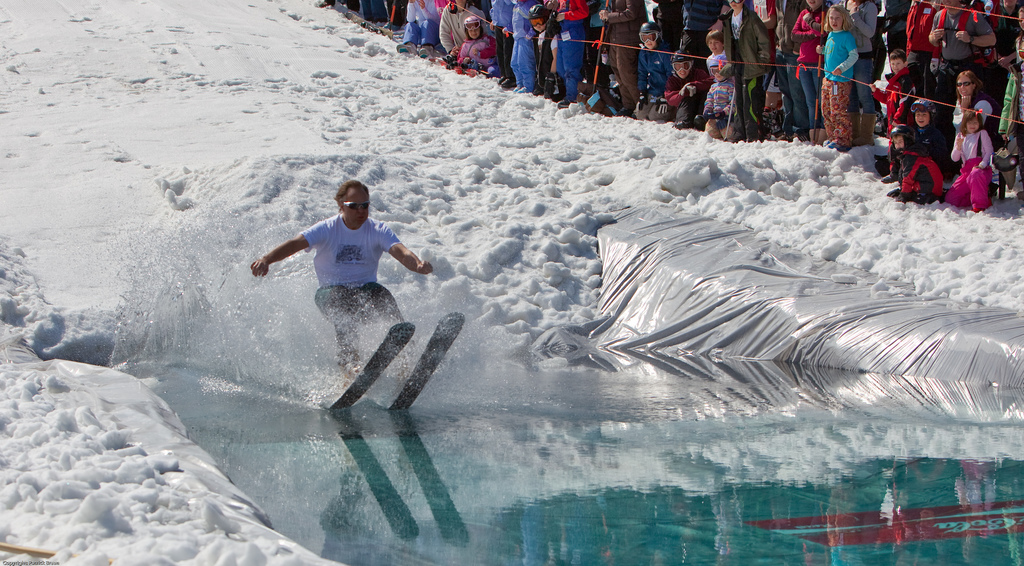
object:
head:
[332, 180, 371, 225]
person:
[945, 110, 994, 213]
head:
[961, 110, 985, 133]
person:
[907, 99, 946, 162]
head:
[911, 98, 938, 126]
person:
[953, 70, 1000, 142]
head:
[953, 70, 980, 98]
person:
[704, 59, 737, 143]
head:
[704, 29, 728, 52]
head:
[710, 60, 732, 82]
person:
[706, 29, 730, 82]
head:
[673, 48, 697, 79]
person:
[663, 50, 712, 131]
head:
[638, 22, 660, 50]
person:
[638, 22, 673, 120]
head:
[465, 16, 482, 40]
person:
[458, 15, 497, 77]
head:
[529, 13, 546, 31]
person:
[526, 14, 558, 99]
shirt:
[299, 214, 401, 288]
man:
[250, 180, 464, 406]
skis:
[331, 312, 460, 414]